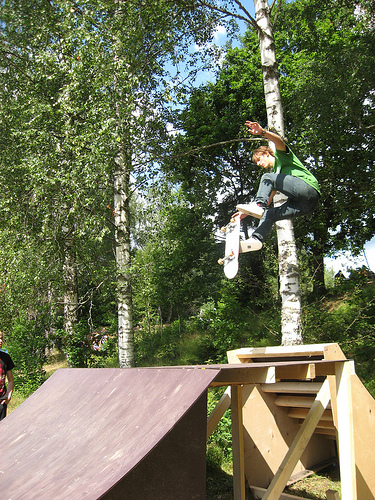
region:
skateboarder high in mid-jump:
[206, 115, 323, 280]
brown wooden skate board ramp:
[4, 361, 217, 498]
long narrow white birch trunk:
[250, 0, 320, 345]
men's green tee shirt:
[268, 137, 327, 198]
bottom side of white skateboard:
[217, 213, 247, 279]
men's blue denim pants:
[252, 170, 323, 245]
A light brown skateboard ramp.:
[225, 341, 370, 496]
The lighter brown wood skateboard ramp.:
[225, 342, 373, 497]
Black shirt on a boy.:
[0, 352, 14, 401]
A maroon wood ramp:
[1, 367, 222, 497]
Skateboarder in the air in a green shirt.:
[233, 120, 319, 253]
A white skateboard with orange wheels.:
[219, 211, 242, 279]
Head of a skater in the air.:
[250, 147, 275, 169]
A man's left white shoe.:
[235, 203, 265, 220]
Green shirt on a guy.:
[270, 146, 321, 197]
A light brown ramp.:
[226, 342, 373, 498]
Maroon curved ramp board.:
[0, 368, 219, 498]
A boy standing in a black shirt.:
[0, 332, 15, 419]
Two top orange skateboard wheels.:
[220, 215, 235, 231]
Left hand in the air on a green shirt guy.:
[243, 119, 261, 135]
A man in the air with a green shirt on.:
[236, 120, 321, 252]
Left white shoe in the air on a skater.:
[235, 200, 264, 219]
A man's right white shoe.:
[237, 235, 263, 254]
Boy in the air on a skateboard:
[215, 120, 321, 279]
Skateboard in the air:
[219, 215, 239, 279]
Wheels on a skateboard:
[208, 250, 232, 265]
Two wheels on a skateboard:
[214, 216, 233, 231]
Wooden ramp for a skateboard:
[3, 368, 220, 494]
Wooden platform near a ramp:
[147, 360, 348, 382]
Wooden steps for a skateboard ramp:
[231, 343, 372, 499]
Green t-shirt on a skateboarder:
[272, 145, 321, 192]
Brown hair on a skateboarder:
[253, 143, 271, 154]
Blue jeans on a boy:
[255, 172, 318, 236]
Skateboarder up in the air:
[213, 121, 321, 279]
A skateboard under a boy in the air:
[215, 213, 242, 279]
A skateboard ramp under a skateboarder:
[3, 367, 216, 498]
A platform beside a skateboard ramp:
[141, 356, 346, 374]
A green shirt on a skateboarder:
[271, 144, 322, 189]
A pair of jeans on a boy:
[257, 172, 318, 237]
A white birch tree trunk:
[273, 225, 304, 342]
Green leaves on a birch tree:
[33, 36, 139, 238]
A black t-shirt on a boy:
[1, 352, 13, 395]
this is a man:
[180, 77, 368, 283]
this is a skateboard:
[201, 192, 263, 286]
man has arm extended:
[231, 111, 298, 161]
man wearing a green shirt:
[249, 130, 324, 187]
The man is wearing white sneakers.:
[235, 196, 271, 224]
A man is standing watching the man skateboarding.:
[0, 336, 15, 413]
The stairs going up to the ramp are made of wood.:
[209, 343, 371, 499]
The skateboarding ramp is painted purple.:
[5, 360, 211, 494]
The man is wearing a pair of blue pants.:
[242, 172, 315, 240]